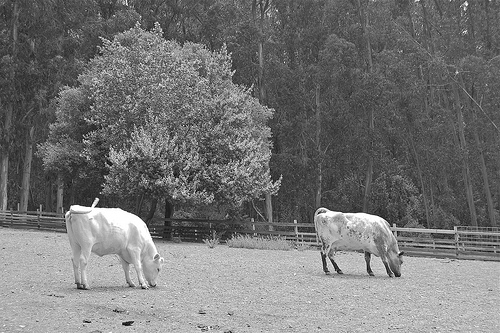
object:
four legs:
[70, 241, 150, 292]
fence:
[475, 230, 500, 260]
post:
[453, 226, 460, 260]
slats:
[412, 227, 448, 235]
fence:
[254, 218, 294, 247]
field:
[377, 288, 498, 332]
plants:
[224, 230, 245, 248]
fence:
[0, 208, 36, 230]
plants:
[292, 238, 314, 250]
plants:
[201, 232, 226, 248]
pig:
[313, 203, 405, 280]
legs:
[362, 251, 377, 275]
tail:
[314, 205, 329, 247]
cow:
[64, 197, 165, 290]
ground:
[355, 138, 412, 186]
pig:
[53, 195, 166, 296]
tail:
[61, 195, 101, 215]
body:
[88, 206, 135, 254]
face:
[142, 260, 163, 287]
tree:
[31, 19, 286, 242]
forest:
[273, 0, 415, 231]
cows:
[312, 206, 405, 278]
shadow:
[91, 284, 138, 291]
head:
[134, 243, 170, 303]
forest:
[0, 0, 36, 231]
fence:
[395, 226, 454, 260]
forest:
[400, 0, 498, 260]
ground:
[205, 258, 284, 316]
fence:
[454, 223, 500, 261]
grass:
[227, 226, 301, 252]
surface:
[205, 276, 306, 312]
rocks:
[198, 311, 207, 316]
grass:
[0, 243, 67, 332]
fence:
[172, 218, 249, 246]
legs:
[316, 240, 330, 273]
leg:
[130, 240, 153, 289]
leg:
[126, 242, 150, 290]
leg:
[77, 237, 95, 293]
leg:
[73, 246, 82, 291]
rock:
[198, 311, 206, 315]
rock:
[113, 308, 125, 314]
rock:
[82, 319, 91, 323]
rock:
[122, 320, 134, 326]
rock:
[227, 312, 234, 316]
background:
[275, 86, 489, 142]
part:
[433, 175, 451, 200]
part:
[426, 234, 435, 248]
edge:
[277, 174, 283, 180]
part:
[446, 234, 460, 248]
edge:
[436, 260, 440, 263]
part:
[290, 295, 291, 302]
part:
[350, 174, 353, 183]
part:
[252, 281, 259, 295]